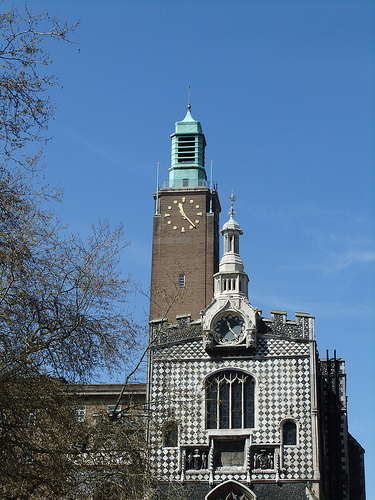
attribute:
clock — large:
[164, 195, 204, 232]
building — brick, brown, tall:
[147, 82, 220, 322]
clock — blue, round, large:
[215, 312, 245, 343]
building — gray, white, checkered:
[147, 191, 366, 499]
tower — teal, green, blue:
[168, 85, 210, 186]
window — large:
[205, 368, 257, 430]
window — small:
[177, 270, 189, 289]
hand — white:
[229, 328, 239, 338]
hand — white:
[224, 321, 232, 330]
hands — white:
[175, 201, 197, 229]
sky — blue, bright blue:
[3, 3, 375, 399]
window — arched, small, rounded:
[279, 417, 300, 447]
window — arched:
[162, 419, 180, 450]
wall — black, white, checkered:
[148, 338, 314, 480]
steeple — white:
[212, 186, 251, 298]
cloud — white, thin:
[258, 295, 372, 322]